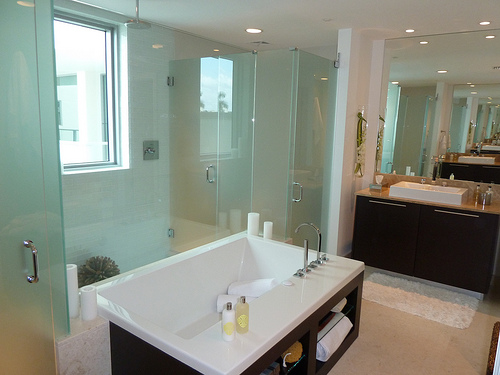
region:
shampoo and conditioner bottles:
[222, 295, 248, 339]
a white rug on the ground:
[362, 270, 477, 327]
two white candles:
[64, 261, 96, 318]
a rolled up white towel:
[314, 313, 354, 363]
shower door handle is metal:
[293, 180, 303, 202]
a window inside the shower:
[54, 18, 126, 170]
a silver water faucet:
[293, 223, 328, 276]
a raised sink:
[386, 180, 468, 204]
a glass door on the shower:
[251, 49, 326, 250]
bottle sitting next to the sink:
[474, 183, 492, 205]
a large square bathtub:
[82, 229, 365, 373]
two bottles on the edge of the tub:
[219, 294, 249, 341]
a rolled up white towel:
[318, 315, 352, 360]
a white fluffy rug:
[362, 269, 483, 330]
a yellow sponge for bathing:
[286, 341, 303, 361]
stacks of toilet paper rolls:
[65, 262, 97, 322]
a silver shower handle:
[22, 238, 42, 285]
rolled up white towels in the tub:
[212, 276, 283, 314]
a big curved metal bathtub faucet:
[293, 220, 326, 276]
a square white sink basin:
[391, 177, 468, 210]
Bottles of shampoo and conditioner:
[222, 299, 249, 341]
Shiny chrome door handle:
[17, 238, 44, 282]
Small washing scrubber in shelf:
[282, 334, 306, 366]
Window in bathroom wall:
[51, 1, 133, 173]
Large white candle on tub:
[246, 211, 257, 233]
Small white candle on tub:
[262, 218, 274, 240]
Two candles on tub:
[62, 261, 97, 318]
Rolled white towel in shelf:
[315, 311, 351, 361]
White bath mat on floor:
[360, 270, 483, 330]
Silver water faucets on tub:
[295, 221, 325, 271]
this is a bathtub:
[108, 201, 345, 373]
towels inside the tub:
[180, 259, 307, 319]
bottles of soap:
[211, 285, 304, 370]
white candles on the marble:
[55, 239, 115, 345]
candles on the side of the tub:
[240, 201, 302, 256]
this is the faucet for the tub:
[273, 207, 363, 298]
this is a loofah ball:
[267, 329, 314, 371]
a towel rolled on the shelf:
[308, 296, 376, 371]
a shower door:
[253, 29, 378, 275]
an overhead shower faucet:
[108, 0, 182, 66]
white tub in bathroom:
[67, 201, 335, 371]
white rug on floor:
[374, 260, 464, 334]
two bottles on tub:
[204, 293, 256, 341]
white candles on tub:
[237, 210, 273, 253]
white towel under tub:
[302, 315, 362, 365]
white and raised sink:
[380, 150, 475, 215]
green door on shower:
[40, 61, 246, 301]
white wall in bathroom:
[315, 51, 359, 243]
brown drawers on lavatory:
[344, 190, 494, 301]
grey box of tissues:
[355, 155, 385, 209]